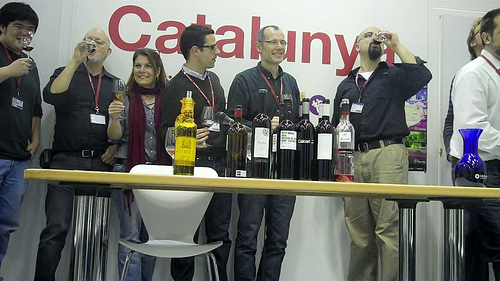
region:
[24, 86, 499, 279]
wine bottles are arranged on the table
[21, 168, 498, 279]
table slab is made of wood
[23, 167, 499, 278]
table has four silver legs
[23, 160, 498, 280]
a chair is placed in front of the table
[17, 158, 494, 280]
table is in front of the white chair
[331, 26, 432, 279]
the person is drinking the wine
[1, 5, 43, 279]
the guy is holding the wine glass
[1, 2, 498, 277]
people are wearing a tag around their neck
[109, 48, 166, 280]
the woman with red scarf around her neck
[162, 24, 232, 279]
the person is looking towards his left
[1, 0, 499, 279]
people standing behind the table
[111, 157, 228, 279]
a white chair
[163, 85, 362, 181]
bottles of wine on the table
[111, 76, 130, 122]
a glass of wine the woman is holding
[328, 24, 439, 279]
a person drinking wine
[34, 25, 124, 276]
a person drinking wine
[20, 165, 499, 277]
a long table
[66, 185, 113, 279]
legs of the table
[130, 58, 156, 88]
a face of a woman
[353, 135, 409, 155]
a belt the guy is wearing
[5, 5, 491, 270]
people standing behind table and chair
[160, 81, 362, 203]
bottles of liquor on top of a table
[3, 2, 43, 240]
man smiling with wine glass to face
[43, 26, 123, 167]
man drinking from lifted wine glass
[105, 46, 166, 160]
woman looking ahead while holding glass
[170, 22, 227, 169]
man with eyeglasses turned to side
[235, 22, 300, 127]
man with eyeglasses looking straight ahead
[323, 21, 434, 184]
man drinking with head tilted back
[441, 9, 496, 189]
deep blue vase in front of people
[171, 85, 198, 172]
yellow bottle on wooden table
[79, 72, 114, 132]
red lanyard with white tag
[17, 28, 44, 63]
clear glass of red wine sip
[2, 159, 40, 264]
blue jeans worn by Asian man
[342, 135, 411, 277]
khaki pants on man holding can to mouth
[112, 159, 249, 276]
white modern chair behind chair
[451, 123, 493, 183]
blue carafe sitting on table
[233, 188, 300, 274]
man wearing blue jeans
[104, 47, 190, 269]
woman with red scarf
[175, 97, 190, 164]
a bottle with liquid in it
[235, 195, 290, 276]
man wearing grey pants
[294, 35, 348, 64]
letters are red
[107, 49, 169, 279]
woman drinking a glass of wine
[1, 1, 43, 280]
man drinking a glass of wine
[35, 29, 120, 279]
man drinking a glass of wine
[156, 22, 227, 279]
man holding a glass of wine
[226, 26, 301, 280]
man holding a glass of wine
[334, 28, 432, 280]
man drinking a glass of wine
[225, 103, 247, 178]
a bottle of wine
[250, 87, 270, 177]
a bottle of wine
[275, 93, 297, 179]
a bottle of wine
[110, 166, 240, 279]
A white chair with silver framing.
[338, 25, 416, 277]
A man drinking out of a glass.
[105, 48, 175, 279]
A woman holding up a wine glass.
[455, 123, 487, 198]
A blue vase.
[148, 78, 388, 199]
Bottles on top of a table.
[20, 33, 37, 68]
A wine glass.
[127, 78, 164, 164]
A burgundy scarf.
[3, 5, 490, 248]
People tasting wine.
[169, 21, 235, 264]
A man with black hair.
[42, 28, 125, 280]
Man in glasses is drinking from wine glass.